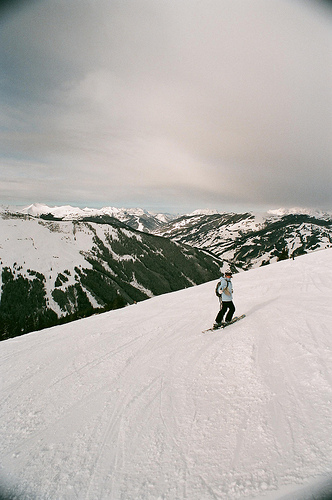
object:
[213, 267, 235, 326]
person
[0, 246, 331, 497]
slope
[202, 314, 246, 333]
skis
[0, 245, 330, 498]
ice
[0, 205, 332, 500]
snow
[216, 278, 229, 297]
backpack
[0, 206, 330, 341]
mountains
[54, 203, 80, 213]
snow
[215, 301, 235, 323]
pants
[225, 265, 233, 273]
helmet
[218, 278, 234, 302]
jacket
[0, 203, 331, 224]
mountaintop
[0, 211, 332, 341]
ranges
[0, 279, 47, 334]
trees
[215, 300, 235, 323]
black pants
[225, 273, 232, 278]
glasses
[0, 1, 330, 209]
sky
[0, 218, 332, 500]
ground